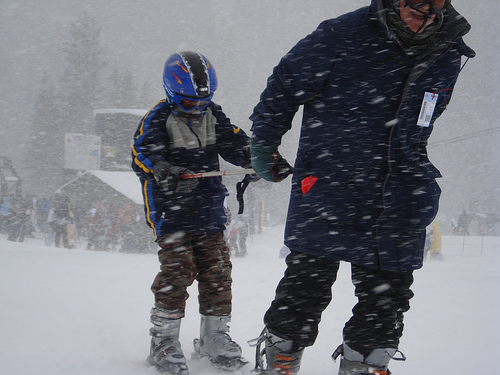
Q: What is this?
A: Skating.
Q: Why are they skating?
A: Fun.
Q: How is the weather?
A: Snowy.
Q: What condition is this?
A: Blizzard.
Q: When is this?
A: Daytime.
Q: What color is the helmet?
A: Blue.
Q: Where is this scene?
A: Mountain.